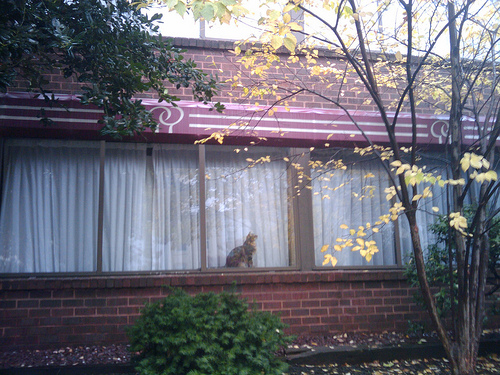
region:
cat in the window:
[207, 219, 289, 274]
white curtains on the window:
[112, 150, 149, 256]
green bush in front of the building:
[115, 279, 320, 374]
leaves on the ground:
[345, 350, 427, 372]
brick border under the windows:
[287, 272, 344, 282]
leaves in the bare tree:
[392, 156, 442, 197]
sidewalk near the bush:
[316, 353, 371, 373]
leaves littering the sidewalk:
[23, 350, 94, 372]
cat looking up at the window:
[223, 220, 274, 277]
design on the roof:
[151, 104, 189, 132]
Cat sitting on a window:
[220, 218, 264, 270]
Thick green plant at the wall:
[121, 282, 299, 374]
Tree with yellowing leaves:
[131, 2, 498, 374]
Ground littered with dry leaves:
[0, 329, 499, 374]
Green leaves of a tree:
[1, 0, 228, 154]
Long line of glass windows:
[0, 137, 499, 274]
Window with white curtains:
[0, 137, 499, 273]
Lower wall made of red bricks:
[0, 273, 499, 363]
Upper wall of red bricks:
[1, 37, 499, 122]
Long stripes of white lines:
[1, 91, 498, 144]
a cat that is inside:
[232, 237, 289, 271]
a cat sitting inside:
[217, 215, 293, 307]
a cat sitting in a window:
[207, 212, 296, 298]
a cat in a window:
[223, 205, 275, 272]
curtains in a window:
[204, 207, 317, 327]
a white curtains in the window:
[76, 126, 474, 342]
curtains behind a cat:
[196, 151, 303, 363]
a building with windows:
[179, 76, 386, 255]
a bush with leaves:
[118, 278, 268, 371]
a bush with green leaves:
[158, 272, 315, 368]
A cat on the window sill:
[223, 231, 256, 266]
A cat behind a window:
[225, 230, 255, 262]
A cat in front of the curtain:
[225, 230, 255, 265]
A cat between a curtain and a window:
[225, 232, 258, 266]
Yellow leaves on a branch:
[358, 242, 373, 255]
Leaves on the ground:
[376, 370, 405, 374]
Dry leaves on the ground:
[380, 367, 433, 374]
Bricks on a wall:
[295, 295, 370, 322]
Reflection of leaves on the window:
[164, 199, 195, 241]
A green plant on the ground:
[160, 324, 249, 373]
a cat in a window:
[221, 216, 315, 316]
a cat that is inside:
[204, 187, 289, 297]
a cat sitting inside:
[222, 190, 419, 337]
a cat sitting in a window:
[160, 201, 267, 271]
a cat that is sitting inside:
[209, 191, 311, 316]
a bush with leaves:
[154, 281, 329, 373]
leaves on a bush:
[130, 293, 343, 372]